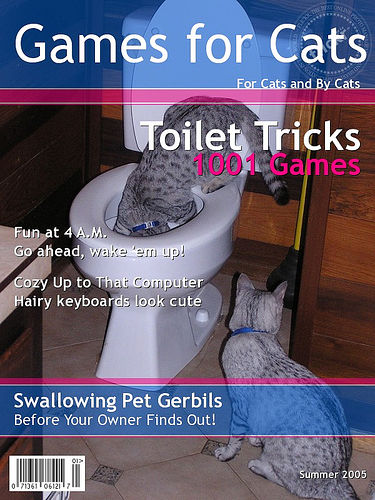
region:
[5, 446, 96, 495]
upc symbol at the bottom left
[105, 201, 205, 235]
Blue collar on the kitty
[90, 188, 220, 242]
kittys head in the toilet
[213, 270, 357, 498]
second kitty waiting in line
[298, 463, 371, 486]
the date the kitty game comes out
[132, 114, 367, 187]
name of the new kitty game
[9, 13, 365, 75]
product line games for cats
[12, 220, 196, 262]
tagline on new kitty game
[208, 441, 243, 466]
left kitty paw on floor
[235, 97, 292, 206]
kitty tail hanging off toilet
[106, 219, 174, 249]
cat is in the toilet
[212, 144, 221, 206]
cat's back legs are on the toilet seat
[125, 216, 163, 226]
cat has a blue collar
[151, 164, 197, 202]
black spots on the cat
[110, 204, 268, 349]
two cats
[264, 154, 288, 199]
cat's tail has stripes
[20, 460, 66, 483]
barcode on the bottom left corner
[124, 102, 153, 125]
toilet seat is up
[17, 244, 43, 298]
counter top in the bathroom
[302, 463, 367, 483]
Summer 2005 in the bottom right corner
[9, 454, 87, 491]
standard product barcode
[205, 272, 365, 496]
spotted four legged animal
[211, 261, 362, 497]
spotted grey cat wearing a blue collar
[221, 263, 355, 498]
cat wearing a blue collar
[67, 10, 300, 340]
cat looking in the toilet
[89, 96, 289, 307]
cat in toilet wearing a blue collar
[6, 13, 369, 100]
title of publication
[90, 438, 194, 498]
tile pattern on floor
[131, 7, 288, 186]
white porcelain toilet lid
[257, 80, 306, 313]
toilet plunger in the corner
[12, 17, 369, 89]
Magazine parody title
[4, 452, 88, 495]
UPC code for magazine parody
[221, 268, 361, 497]
Back view of cat seated on floor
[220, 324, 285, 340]
Blue collar around cat's neck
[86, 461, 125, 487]
Decorative tile on bathroom floor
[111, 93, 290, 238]
Cat with head in toilet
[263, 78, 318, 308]
Toilet plunger in corner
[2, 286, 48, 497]
Wooden bathroom vanity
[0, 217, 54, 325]
Marble top on bathroom vanity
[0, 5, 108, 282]
Wooden bathroom wall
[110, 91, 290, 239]
Cat is in the toilet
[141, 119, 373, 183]
Magazine headline lists the toilet tricks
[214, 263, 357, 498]
The cat is looking at the plunger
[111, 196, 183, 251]
The cat in the toilet has a blue collar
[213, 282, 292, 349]
The cat on the floor has a blue collar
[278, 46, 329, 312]
The toilet plunger has a yellow handle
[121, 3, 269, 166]
The toilet seat is up.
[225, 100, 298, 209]
The cats tail is outside the toilet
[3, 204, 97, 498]
The bathroom has a wicker set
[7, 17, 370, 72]
The magazine is called "Games for Cats"